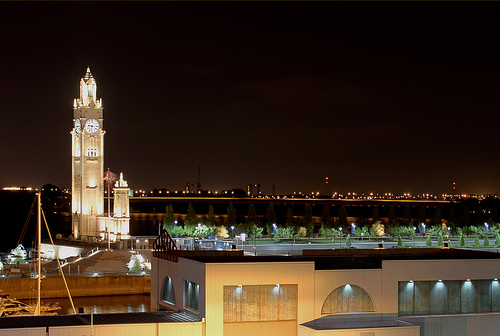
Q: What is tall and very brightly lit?
A: The tower.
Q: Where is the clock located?
A: Close to the top of the tower.